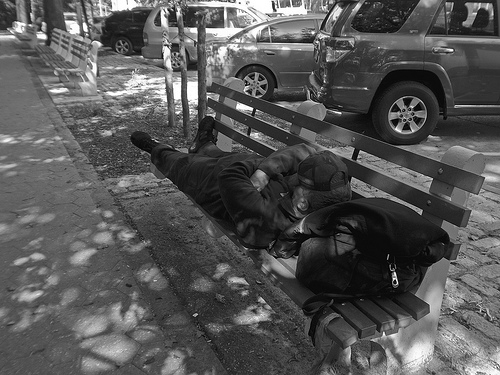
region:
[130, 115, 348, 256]
the man is on the bench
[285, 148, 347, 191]
the man has a hat on his head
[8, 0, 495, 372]
the photo is black and white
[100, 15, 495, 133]
the cars are parked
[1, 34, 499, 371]
the street has cobble stones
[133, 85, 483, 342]
the bench is made of wood slats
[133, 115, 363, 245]
the man is sleeping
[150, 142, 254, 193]
the man is wearing long pants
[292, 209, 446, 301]
the man is using a backpack like a pillow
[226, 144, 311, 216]
the man has is arms crossed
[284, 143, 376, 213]
person wearing a black hat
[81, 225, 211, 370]
sun light on the ground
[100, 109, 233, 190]
a apir of black tennis shoes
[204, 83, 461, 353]
a bench in the cement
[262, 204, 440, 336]
a black bag and jacket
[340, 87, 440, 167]
black tire with silver rim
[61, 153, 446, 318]
person sleeping on a bench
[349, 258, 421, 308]
silver buckle on black bag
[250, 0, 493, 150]
a gray mini van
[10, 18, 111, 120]
benches on a side walk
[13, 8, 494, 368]
Black and white image of a city street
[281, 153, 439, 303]
Person's head resting on backpack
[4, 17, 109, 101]
Row of concrete and wood park benches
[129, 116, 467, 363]
Man sleeping on a bench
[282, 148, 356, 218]
Black baseball cap pulled over sleeping man's eyes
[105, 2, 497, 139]
Four parked cars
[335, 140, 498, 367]
Bricks pavers on the side of a street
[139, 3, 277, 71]
Light colored SUV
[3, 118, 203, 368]
Shadowed ground with patches of sunlight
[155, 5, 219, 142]
Stakes supporting the trunk of a young tree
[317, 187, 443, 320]
black backpack on bench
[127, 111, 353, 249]
a man sleeping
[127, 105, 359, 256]
a man on a bench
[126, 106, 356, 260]
a man laying on a bench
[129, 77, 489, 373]
a man sleeping on a bench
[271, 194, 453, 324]
a black backpack and jacket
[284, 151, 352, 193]
a black hat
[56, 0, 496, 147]
a row of parked cars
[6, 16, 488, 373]
a row of benches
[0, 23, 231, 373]
a concrete sidewalk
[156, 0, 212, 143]
a row of thin trees